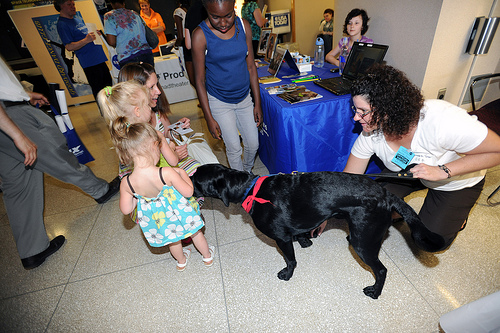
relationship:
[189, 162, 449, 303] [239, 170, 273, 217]
dog wearing tie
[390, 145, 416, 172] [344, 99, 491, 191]
tag on shirt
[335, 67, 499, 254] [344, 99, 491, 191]
woman wearing shirt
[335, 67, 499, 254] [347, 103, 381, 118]
woman wearing glasses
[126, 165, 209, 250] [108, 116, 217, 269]
dress on girl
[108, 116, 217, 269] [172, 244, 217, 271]
girl wearing sandals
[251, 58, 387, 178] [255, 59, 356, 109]
cloth on table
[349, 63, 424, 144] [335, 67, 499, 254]
hair of woman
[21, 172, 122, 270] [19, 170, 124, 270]
man wearing shoes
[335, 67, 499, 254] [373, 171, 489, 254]
woman wearing pants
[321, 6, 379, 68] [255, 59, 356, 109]
woman at table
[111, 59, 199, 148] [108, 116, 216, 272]
woman with girl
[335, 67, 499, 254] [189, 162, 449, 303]
woman holding dog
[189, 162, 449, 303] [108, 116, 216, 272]
dog by girl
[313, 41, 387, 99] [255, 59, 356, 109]
laptop on table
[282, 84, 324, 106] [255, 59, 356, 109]
magazine on table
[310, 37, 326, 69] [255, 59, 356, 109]
water bottle on table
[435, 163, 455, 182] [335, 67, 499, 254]
bracelet on woman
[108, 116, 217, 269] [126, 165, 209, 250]
girl in dress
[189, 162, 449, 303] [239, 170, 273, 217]
dog with tie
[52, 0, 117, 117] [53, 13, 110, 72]
man wearing shirt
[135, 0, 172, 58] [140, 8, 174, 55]
woman wearing shirt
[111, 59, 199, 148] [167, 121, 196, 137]
woman holding card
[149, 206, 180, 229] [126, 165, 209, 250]
flowers on dress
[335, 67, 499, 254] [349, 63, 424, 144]
woman has hair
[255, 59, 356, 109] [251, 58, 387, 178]
table with cloth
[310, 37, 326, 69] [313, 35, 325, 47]
water bottle has top